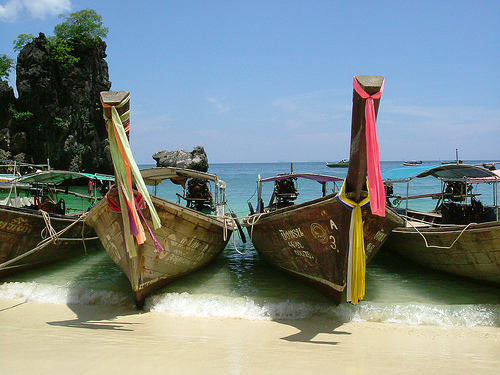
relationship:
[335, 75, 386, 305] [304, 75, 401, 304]
ribbons on front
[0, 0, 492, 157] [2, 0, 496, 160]
clouds in sky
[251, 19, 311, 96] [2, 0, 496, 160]
part of sky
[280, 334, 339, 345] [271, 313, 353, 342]
edge of shade